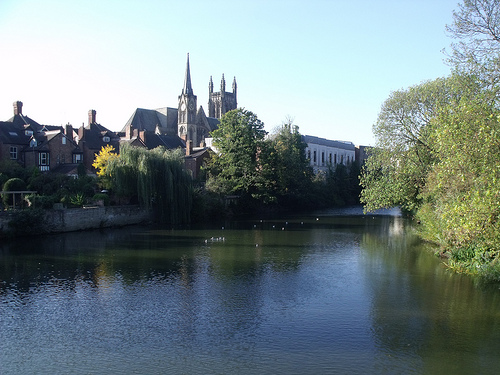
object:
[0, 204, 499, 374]
there is a lake.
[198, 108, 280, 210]
there are trees.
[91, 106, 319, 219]
trees are in group.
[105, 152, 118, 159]
leaves are yellow.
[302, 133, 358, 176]
there is a building.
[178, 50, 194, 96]
steeple is grey.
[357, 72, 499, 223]
there is green tree.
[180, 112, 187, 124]
tower has stripes.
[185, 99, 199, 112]
clock is on tower.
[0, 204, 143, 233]
there is a wall.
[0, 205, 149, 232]
there is a riverbank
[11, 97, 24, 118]
there is a chimney.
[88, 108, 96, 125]
chimney is on roof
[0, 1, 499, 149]
sky is clear.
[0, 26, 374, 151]
sky has clouds.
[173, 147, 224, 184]
there are buildings.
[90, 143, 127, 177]
trees are in front.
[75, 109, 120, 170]
there are homes.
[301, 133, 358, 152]
roof is grey.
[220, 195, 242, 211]
there is a bridge.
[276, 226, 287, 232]
there are birds.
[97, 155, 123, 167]
tree has branch.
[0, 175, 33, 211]
bush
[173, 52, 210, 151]
building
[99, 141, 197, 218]
tree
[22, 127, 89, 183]
house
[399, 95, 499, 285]
trees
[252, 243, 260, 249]
birds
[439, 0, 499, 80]
tree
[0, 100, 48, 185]
home